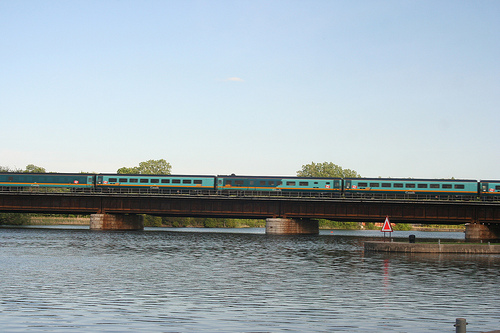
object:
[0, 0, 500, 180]
sky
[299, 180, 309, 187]
window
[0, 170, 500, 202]
train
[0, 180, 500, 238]
bridge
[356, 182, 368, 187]
window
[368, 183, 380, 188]
window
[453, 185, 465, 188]
window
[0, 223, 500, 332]
water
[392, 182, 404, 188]
window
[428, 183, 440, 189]
window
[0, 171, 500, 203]
passenger train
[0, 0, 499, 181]
clouds